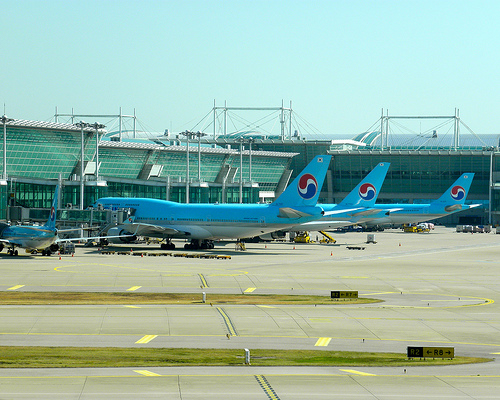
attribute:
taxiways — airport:
[3, 266, 498, 398]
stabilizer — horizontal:
[11, 215, 111, 236]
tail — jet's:
[272, 152, 367, 228]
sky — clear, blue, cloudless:
[251, 28, 399, 76]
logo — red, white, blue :
[292, 174, 319, 207]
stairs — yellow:
[316, 225, 339, 250]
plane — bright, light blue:
[0, 170, 65, 256]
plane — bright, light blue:
[86, 152, 362, 252]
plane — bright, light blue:
[252, 162, 402, 239]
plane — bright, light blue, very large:
[309, 168, 482, 237]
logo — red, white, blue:
[297, 173, 319, 200]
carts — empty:
[453, 220, 492, 234]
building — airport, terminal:
[300, 134, 498, 219]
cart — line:
[101, 222, 251, 277]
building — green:
[0, 117, 495, 224]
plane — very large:
[96, 154, 327, 248]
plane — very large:
[236, 160, 391, 244]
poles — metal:
[441, 100, 474, 176]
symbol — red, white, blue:
[294, 170, 324, 200]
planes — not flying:
[95, 147, 480, 248]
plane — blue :
[49, 117, 321, 275]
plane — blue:
[95, 157, 370, 236]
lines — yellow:
[4, 260, 489, 398]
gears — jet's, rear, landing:
[148, 232, 222, 258]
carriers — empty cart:
[93, 241, 238, 270]